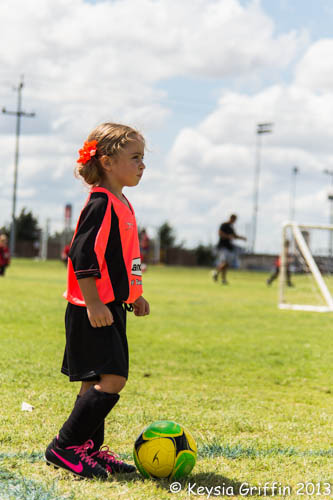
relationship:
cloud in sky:
[297, 40, 331, 96] [4, 0, 332, 248]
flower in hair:
[77, 139, 97, 166] [94, 123, 124, 149]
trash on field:
[7, 382, 48, 425] [0, 256, 331, 499]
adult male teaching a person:
[212, 214, 247, 285] [267, 239, 293, 287]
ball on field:
[129, 410, 206, 484] [123, 316, 324, 482]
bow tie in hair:
[71, 136, 100, 164] [72, 119, 139, 183]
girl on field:
[44, 121, 150, 482] [0, 256, 331, 499]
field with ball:
[0, 256, 331, 499] [132, 417, 197, 482]